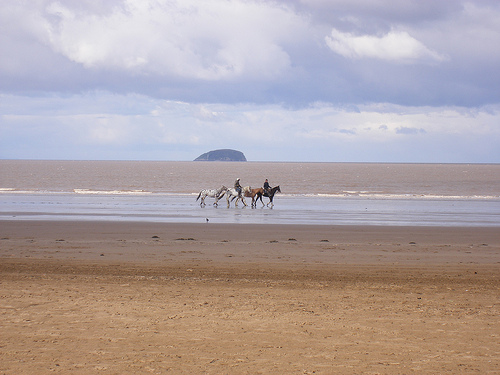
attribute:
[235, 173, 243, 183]
hat — white